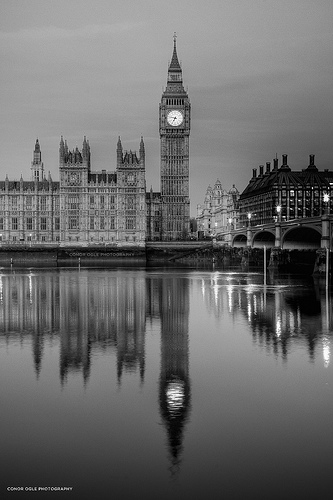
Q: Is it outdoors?
A: Yes, it is outdoors.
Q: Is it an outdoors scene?
A: Yes, it is outdoors.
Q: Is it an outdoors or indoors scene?
A: It is outdoors.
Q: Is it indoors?
A: No, it is outdoors.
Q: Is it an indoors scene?
A: No, it is outdoors.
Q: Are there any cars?
A: No, there are no cars.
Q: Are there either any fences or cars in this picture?
A: No, there are no cars or fences.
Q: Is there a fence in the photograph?
A: No, there are no fences.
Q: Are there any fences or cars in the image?
A: No, there are no fences or cars.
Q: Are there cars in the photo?
A: No, there are no cars.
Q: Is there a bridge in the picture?
A: Yes, there is a bridge.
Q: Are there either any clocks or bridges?
A: Yes, there is a bridge.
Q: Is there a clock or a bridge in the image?
A: Yes, there is a bridge.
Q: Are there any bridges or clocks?
A: Yes, there is a bridge.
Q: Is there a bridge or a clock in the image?
A: Yes, there is a bridge.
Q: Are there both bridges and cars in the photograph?
A: No, there is a bridge but no cars.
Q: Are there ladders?
A: No, there are no ladders.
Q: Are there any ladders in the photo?
A: No, there are no ladders.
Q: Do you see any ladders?
A: No, there are no ladders.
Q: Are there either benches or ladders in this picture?
A: No, there are no ladders or benches.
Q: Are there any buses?
A: No, there are no buses.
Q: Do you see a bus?
A: No, there are no buses.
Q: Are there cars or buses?
A: No, there are no buses or cars.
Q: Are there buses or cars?
A: No, there are no buses or cars.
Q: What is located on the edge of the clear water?
A: The buildings are on the edge of the water.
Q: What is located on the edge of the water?
A: The buildings are on the edge of the water.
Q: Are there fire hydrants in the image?
A: No, there are no fire hydrants.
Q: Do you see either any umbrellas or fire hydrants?
A: No, there are no fire hydrants or umbrellas.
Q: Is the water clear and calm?
A: Yes, the water is clear and calm.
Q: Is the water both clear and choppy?
A: No, the water is clear but calm.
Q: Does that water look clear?
A: Yes, the water is clear.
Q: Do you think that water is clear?
A: Yes, the water is clear.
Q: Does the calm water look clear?
A: Yes, the water is clear.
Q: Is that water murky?
A: No, the water is clear.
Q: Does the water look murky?
A: No, the water is clear.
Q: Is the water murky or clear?
A: The water is clear.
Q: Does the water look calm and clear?
A: Yes, the water is calm and clear.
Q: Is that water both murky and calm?
A: No, the water is calm but clear.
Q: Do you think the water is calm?
A: Yes, the water is calm.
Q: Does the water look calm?
A: Yes, the water is calm.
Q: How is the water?
A: The water is calm.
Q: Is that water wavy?
A: No, the water is calm.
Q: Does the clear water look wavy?
A: No, the water is calm.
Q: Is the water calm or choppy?
A: The water is calm.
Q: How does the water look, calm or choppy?
A: The water is calm.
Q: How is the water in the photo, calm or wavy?
A: The water is calm.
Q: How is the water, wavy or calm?
A: The water is calm.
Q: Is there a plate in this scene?
A: No, there are no plates.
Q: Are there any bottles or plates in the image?
A: No, there are no plates or bottles.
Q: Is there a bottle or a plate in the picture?
A: No, there are no plates or bottles.